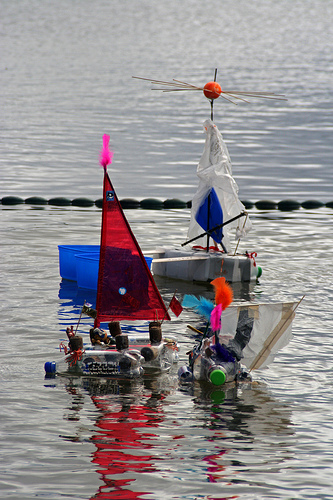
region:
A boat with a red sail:
[83, 174, 174, 335]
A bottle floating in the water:
[46, 344, 152, 385]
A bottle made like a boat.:
[201, 315, 261, 400]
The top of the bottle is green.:
[209, 362, 232, 394]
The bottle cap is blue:
[41, 352, 65, 375]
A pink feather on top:
[92, 128, 142, 173]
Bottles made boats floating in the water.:
[53, 311, 328, 421]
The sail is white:
[196, 133, 275, 244]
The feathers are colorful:
[185, 288, 256, 348]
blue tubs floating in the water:
[48, 239, 165, 289]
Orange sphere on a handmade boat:
[195, 76, 242, 108]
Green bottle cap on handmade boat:
[200, 367, 237, 386]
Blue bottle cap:
[35, 358, 61, 375]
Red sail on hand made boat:
[93, 200, 176, 338]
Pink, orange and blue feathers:
[186, 280, 244, 326]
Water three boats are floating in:
[57, 422, 215, 482]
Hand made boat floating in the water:
[170, 281, 291, 394]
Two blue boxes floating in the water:
[56, 236, 150, 297]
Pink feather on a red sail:
[94, 130, 126, 177]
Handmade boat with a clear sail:
[162, 58, 245, 268]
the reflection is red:
[96, 406, 177, 479]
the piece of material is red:
[98, 182, 171, 315]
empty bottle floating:
[53, 352, 166, 381]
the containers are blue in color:
[56, 246, 96, 289]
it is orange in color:
[203, 282, 233, 306]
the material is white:
[200, 136, 242, 224]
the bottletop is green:
[211, 373, 230, 384]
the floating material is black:
[147, 191, 251, 209]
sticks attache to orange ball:
[161, 78, 283, 105]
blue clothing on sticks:
[191, 196, 232, 239]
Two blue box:
[57, 227, 125, 294]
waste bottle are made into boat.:
[66, 218, 274, 434]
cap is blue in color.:
[40, 358, 60, 379]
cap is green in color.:
[206, 358, 228, 391]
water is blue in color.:
[38, 397, 191, 492]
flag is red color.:
[95, 213, 186, 336]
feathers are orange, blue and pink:
[189, 277, 239, 337]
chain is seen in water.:
[2, 185, 332, 225]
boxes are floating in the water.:
[55, 240, 162, 307]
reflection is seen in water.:
[53, 388, 293, 487]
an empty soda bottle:
[36, 345, 146, 386]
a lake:
[4, 397, 330, 497]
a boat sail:
[99, 174, 174, 329]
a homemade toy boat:
[50, 68, 259, 290]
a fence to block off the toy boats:
[0, 192, 328, 221]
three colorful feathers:
[170, 281, 235, 332]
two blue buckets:
[55, 231, 156, 305]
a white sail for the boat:
[224, 301, 295, 374]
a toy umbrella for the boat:
[131, 58, 291, 109]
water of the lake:
[3, 7, 327, 144]